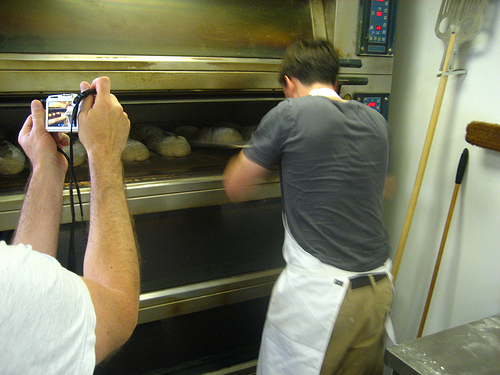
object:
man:
[1, 77, 140, 374]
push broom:
[465, 121, 500, 154]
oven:
[1, 1, 393, 375]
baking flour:
[385, 314, 499, 374]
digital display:
[368, 0, 388, 53]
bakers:
[223, 36, 397, 374]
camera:
[45, 93, 82, 131]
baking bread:
[0, 139, 25, 181]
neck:
[307, 88, 342, 99]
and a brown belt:
[350, 271, 386, 291]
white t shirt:
[0, 242, 96, 375]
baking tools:
[391, 1, 497, 373]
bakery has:
[1, 0, 498, 374]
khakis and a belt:
[282, 271, 394, 374]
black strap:
[56, 87, 96, 271]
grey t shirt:
[241, 97, 388, 273]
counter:
[389, 317, 497, 367]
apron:
[256, 215, 397, 375]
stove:
[3, 1, 322, 373]